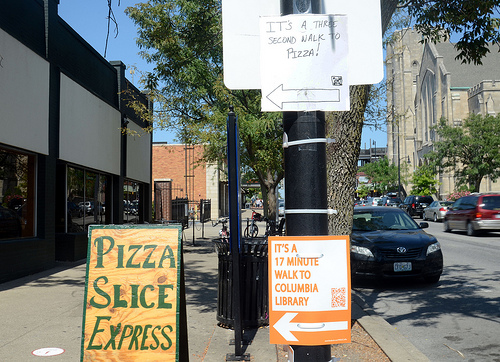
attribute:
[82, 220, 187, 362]
board — express, mini, small, showing, pizza sign, written, orange, white, directional, trimmed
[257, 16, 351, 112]
paper — white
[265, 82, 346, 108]
arrow — small, directional, white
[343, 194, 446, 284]
car — beautiful, parked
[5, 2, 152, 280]
building — big, brick, brown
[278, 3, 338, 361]
pole — black, zip tied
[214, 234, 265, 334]
trash bin — metal, black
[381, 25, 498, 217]
church — large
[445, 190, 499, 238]
van — red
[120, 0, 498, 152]
tree — shadowing, green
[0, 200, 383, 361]
sidewalk — empty, shadowed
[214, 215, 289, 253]
bicycles — parked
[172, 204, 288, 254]
fence — chain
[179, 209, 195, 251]
person — walking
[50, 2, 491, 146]
sky — clear